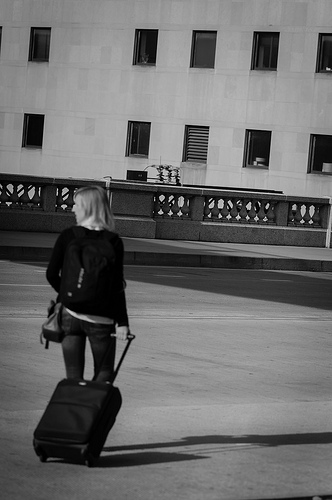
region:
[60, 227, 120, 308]
Black backpack on a woman.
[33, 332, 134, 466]
Black suitcase being pulled behind with a long extended handle.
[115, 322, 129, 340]
A woman's right hand pulling a suitcase.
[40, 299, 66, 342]
Purse on a woman's hip.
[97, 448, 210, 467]
Dark shadow of the suitcase.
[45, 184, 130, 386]
A blonde haired woman in black pulling a suitcase.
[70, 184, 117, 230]
Blonde hair on a woman.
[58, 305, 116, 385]
Dark jeans a woman is wearing.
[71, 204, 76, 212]
Nose on the face of a blonde woman.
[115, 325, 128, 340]
Right hand of a blonde woman.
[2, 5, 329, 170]
windows on side of building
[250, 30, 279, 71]
square window on building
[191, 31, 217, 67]
window glass in square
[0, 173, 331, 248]
stone railing on sidewalk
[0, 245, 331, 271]
curb on side of street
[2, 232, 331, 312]
shadow on top of street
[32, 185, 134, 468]
back of walking woman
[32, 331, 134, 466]
luggage handle in hand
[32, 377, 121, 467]
tilted luggage on wheels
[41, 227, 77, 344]
bag hanging from shoulder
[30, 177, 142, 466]
woman with luggage in hand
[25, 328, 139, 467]
luggage with wheels on it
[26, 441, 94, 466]
wheels on the luggage piece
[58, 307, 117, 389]
pants on the woman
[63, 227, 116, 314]
backpack on the woman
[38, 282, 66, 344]
bag on woman's shoulder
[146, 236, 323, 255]
sidewalk across from woman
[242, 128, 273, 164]
window on the building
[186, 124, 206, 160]
window with blinds partially closed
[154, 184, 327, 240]
decorative wall area near sidewalk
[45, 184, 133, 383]
A woman holding a bag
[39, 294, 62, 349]
A small leather handbag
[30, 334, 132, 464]
A large suitcase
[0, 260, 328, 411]
an asphalt road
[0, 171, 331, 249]
a short stone wall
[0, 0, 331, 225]
A large stone building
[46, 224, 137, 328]
a dark jacket on a woman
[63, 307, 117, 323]
a white shirt on a woman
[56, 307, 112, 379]
a pair of jeans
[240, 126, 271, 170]
a window on a building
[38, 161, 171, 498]
a woman pulling a suitcase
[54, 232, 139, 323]
the backpack is black